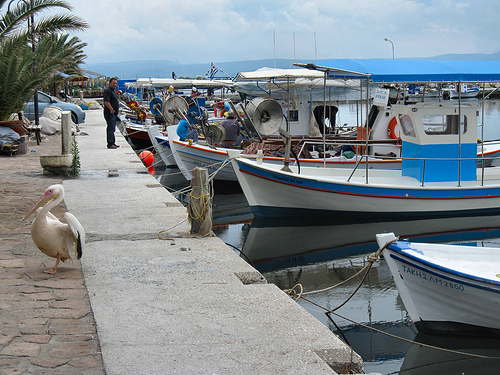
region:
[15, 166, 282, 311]
pelican standing on a boat dock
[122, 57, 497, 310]
boats lined at a boat dock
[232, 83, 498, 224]
red, white, and blue boat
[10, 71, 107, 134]
blue car parked by a boat dock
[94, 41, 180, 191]
man standing on a boat dock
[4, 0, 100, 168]
green palm tree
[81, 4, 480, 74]
blue sky and white clouds in the background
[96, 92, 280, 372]
concrete boat dock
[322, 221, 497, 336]
red white and blue boat docked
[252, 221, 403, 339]
ropes attached to a boat and a dock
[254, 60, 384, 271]
a boat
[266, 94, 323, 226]
a boat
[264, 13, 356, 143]
a boat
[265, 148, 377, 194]
a boat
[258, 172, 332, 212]
a boat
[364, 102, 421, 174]
a boat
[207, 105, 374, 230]
a boat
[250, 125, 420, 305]
a boat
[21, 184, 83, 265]
the bird on the walkway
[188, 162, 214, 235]
the wooden post with rope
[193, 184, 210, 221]
the rope on the wooden post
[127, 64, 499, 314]
the boats in the water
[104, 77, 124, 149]
the man standing near the boats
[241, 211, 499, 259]
the reflection in the water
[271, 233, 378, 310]
the dark colored water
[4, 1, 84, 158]
the trees in front of the boats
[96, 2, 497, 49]
the clouds in the sky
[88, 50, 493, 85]
the mountains in the distance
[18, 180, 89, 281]
Bird on a stone walkway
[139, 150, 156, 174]
Orange bumper on a dock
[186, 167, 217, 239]
Wooden post on a dock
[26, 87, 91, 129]
Blue car parked on a dock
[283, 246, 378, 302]
Roped tied on a boat and dock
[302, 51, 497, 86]
Blue canopy over a boat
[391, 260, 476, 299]
Blue letters on a white boat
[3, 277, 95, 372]
Stones paved in a walkway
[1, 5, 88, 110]
Leaves on a tree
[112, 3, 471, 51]
White clouds in a blue sky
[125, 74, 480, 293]
The boats are docked on the pier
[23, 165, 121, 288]
A pelican poses for a picture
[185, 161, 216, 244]
Boat is tied to the wood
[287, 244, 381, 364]
Rope hanging from the boat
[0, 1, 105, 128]
Palm tree by the dock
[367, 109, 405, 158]
Boat has a safety preserve on it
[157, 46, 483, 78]
Mountains in the background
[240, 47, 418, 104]
Canopy on the boat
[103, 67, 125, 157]
Man standing on the sidewalk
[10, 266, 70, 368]
Brick walkway concrete together